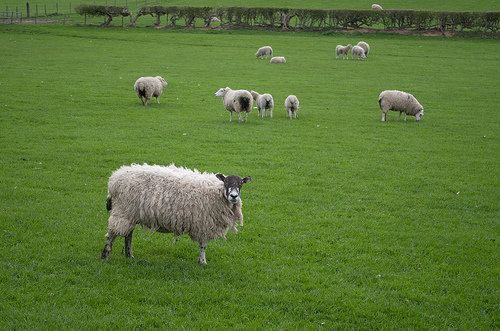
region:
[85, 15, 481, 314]
a small herd of sheep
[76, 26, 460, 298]
the sheep are in the grass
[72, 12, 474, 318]
the sheep are in a field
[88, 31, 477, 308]
they are on a large grass lawn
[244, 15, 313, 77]
they are eating grass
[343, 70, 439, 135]
the sheep is grazing the field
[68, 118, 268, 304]
the sheep is wooly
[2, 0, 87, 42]
this is a fence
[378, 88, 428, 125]
White sheep in field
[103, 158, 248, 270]
Fuzzy white sheep in field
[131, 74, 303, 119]
Four sheep in field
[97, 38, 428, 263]
Herd of sheep in a field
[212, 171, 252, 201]
Black head on white sheep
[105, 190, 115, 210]
Tail on white sheep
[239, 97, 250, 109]
Black tail on white sheep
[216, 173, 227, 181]
Ear on white sheep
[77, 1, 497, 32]
Line of short trees dividing field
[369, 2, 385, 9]
Sheep on far side of trees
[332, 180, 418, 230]
a green grass on the ground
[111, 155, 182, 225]
a white sheep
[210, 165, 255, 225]
a white and black headed sheep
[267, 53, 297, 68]
a sheep laying on the ground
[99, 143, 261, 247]
a sheep with white feathers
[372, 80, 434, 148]
a sheep grazing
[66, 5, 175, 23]
plants along the fence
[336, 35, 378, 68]
white sheep grazing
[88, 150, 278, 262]
sheep staring on the picture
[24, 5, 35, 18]
a black pool on the fence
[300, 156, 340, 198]
short green and brown grass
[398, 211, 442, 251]
short green and brown grass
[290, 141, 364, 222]
short green and brown grass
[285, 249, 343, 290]
short green and brown grass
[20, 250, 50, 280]
short green and brown grass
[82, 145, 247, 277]
gray sheep in green field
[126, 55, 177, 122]
gray sheep in green field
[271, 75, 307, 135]
gray sheep in green field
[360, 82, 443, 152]
gray sheep in green field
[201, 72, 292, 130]
gray sheep in green field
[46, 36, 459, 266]
several sheep in a pasture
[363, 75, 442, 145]
a sheep eating grass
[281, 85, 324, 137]
a sheep eating grass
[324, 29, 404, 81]
three sheep in a pasture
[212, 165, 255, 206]
the head of a sheep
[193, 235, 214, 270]
the front legs of a sheep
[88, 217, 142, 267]
the back legs of a sheep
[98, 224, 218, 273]
the legs of a sheep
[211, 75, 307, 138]
three sheep standing on grass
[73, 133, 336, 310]
a sheep standing on grass